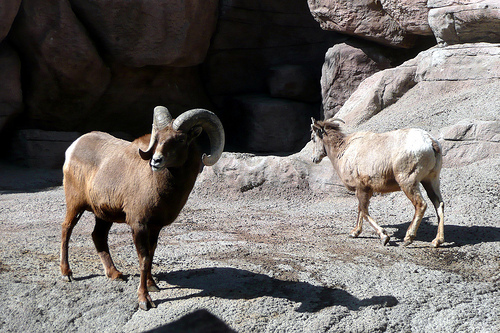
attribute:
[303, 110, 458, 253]
ram — standing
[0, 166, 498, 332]
ground — silver, rocky, gray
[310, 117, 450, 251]
animal — brown, ram, goat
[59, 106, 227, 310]
ram — brown, standing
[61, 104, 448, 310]
rams — standing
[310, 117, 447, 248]
ram — white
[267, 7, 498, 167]
rocks — back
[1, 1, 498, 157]
wall — rock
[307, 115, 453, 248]
goat — brown, white